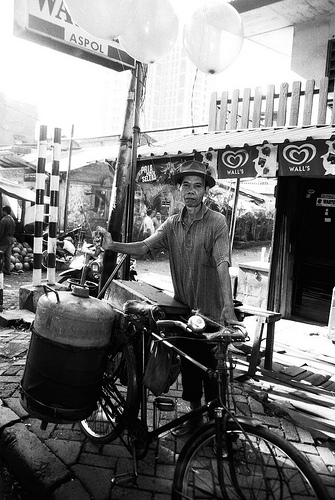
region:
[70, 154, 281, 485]
Livelihood depends bicycle transportation.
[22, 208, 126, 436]
Helium canister back bicycle.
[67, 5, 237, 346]
Man sells helium balloons.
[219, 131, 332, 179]
Heart icon advertizing Wall's.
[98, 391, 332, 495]
Brick pavement under bicycle.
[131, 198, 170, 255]
Group men seen background.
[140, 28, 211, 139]
Highrise building hazy distance.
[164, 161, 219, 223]
Determined look man's face.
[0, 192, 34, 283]
Goods ground for sale.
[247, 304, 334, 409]
Debris left litters street.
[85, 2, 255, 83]
three ballons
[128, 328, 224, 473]
A bicycle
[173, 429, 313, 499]
the front tire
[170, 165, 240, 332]
a man standing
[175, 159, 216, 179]
the man is wearing a hat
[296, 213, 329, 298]
a door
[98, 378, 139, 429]
back tire of bicycle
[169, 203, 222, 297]
man is wearing a collard shirt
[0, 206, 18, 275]
a person standing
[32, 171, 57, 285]
striped poles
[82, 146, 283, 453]
man standing behind bike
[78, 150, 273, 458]
man wearing hat with wide brim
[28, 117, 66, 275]
two poles with wide stripes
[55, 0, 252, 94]
full floating balloons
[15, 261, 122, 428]
large tank on side of bike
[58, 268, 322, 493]
man's bicycle with tank and other containers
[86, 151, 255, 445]
man wearing collared shirt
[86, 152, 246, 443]
man wearing sandals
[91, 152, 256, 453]
man standing on brick pathway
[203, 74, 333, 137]
wooden railing for second story balcony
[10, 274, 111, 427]
A tank on the bike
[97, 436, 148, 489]
A bike pedal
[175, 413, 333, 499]
the front tire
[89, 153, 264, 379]
A man holds up the bike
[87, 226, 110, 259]
The knozzle of the tank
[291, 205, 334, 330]
the door to the buliding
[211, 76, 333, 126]
a wood picket fence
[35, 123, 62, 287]
Stripped posts standing up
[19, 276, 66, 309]
The block for the post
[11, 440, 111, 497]
The stone brick sidewalk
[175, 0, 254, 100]
translucent balloon in the air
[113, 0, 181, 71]
translucent balloon in the air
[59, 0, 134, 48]
translucent balloon in the air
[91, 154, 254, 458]
person wearing a hat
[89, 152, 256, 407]
person wearing a shirt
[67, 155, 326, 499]
person holding a bike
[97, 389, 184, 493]
pedals on a bike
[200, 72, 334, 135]
wooden fence on a balcony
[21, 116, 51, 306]
black and white striped pole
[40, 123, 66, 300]
black and white striped pole